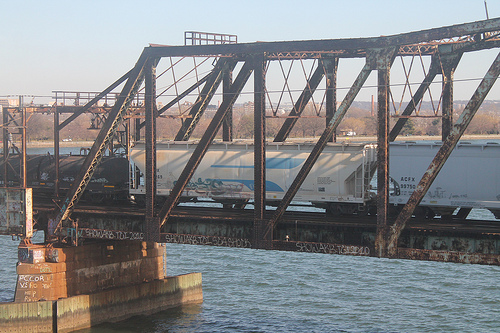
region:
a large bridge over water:
[13, 29, 498, 276]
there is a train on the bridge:
[9, 113, 497, 227]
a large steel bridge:
[20, 8, 495, 268]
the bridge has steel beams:
[50, 33, 499, 230]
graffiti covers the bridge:
[45, 200, 496, 255]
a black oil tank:
[2, 138, 134, 213]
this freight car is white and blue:
[110, 124, 380, 215]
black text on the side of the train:
[388, 168, 423, 198]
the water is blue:
[172, 248, 497, 312]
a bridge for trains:
[2, 13, 497, 268]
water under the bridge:
[173, 255, 460, 331]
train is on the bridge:
[4, 142, 494, 217]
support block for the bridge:
[5, 238, 250, 326]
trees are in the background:
[11, 96, 499, 158]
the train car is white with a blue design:
[130, 138, 385, 208]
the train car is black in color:
[5, 140, 140, 196]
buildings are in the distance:
[3, 92, 192, 114]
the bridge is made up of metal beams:
[146, 40, 498, 137]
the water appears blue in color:
[216, 253, 479, 330]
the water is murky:
[221, 262, 331, 316]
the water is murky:
[222, 268, 384, 327]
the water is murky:
[219, 271, 379, 323]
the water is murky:
[222, 272, 365, 323]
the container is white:
[108, 127, 418, 228]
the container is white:
[117, 125, 365, 222]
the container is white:
[125, 128, 370, 215]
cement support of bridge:
[0, 250, 195, 327]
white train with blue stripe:
[124, 147, 378, 208]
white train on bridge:
[387, 144, 494, 214]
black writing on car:
[391, 174, 428, 199]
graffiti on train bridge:
[52, 213, 371, 255]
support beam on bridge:
[51, 64, 146, 221]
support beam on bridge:
[143, 61, 258, 221]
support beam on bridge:
[267, 55, 378, 230]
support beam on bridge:
[375, 51, 495, 218]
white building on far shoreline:
[61, 137, 73, 142]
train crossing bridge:
[8, 141, 497, 202]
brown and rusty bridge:
[9, 28, 498, 269]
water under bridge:
[180, 250, 498, 318]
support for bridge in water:
[0, 244, 212, 328]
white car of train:
[127, 145, 371, 211]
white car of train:
[383, 136, 497, 216]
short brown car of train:
[0, 152, 130, 200]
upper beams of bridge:
[140, 24, 497, 65]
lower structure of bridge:
[0, 198, 497, 262]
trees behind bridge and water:
[10, 101, 495, 139]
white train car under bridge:
[114, 123, 412, 213]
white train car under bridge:
[109, 123, 406, 203]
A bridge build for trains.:
[2, 3, 499, 283]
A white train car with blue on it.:
[125, 128, 380, 223]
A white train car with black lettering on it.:
[380, 130, 499, 228]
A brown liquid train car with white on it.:
[4, 131, 132, 216]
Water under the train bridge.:
[162, 241, 499, 326]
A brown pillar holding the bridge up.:
[0, 233, 204, 330]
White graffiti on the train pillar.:
[12, 270, 53, 291]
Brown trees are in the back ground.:
[3, 104, 498, 131]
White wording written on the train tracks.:
[64, 223, 494, 273]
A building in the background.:
[3, 93, 22, 113]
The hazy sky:
[5, 2, 494, 97]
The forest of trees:
[9, 97, 499, 142]